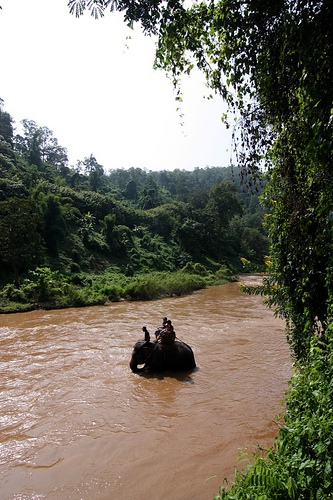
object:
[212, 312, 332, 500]
foliage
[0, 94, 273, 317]
forrest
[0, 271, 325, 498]
river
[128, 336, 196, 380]
elephant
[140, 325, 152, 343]
people